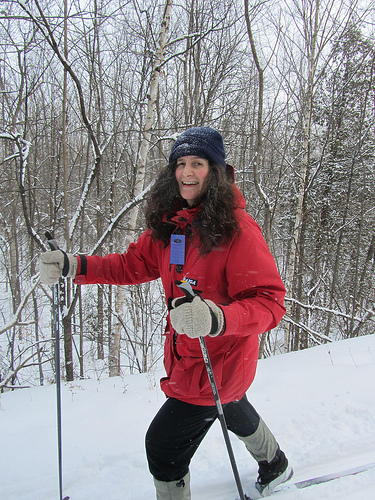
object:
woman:
[39, 125, 293, 497]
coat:
[72, 163, 286, 406]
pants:
[143, 396, 228, 498]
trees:
[109, 0, 173, 378]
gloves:
[169, 279, 224, 339]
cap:
[169, 126, 227, 168]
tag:
[170, 234, 186, 265]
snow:
[0, 383, 60, 498]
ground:
[0, 333, 375, 498]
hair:
[145, 158, 242, 259]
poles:
[173, 279, 250, 500]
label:
[183, 277, 198, 286]